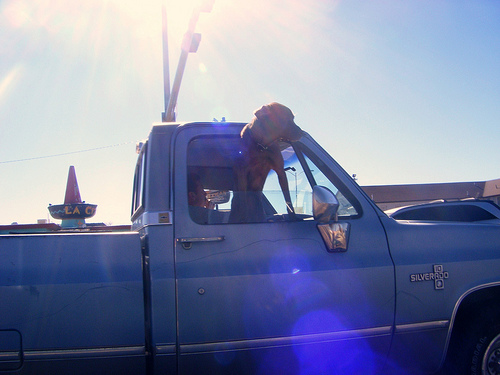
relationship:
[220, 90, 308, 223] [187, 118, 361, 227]
dog in window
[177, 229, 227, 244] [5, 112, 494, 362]
handle on truck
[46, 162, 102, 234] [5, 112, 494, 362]
sign by truck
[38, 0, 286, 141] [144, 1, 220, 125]
sun by pole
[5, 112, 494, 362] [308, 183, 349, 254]
truck has mirror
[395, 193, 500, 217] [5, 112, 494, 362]
vehicle by truck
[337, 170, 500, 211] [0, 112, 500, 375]
building past truck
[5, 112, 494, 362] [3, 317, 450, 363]
truck has stripe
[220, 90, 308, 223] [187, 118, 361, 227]
dog looking out window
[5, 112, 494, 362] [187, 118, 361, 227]
truck has window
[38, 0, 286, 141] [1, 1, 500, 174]
sun has sunshine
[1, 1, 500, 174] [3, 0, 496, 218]
sunshine visible in sky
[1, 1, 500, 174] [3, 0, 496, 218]
sunshine in sky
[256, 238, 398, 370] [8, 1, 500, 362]
circles on photo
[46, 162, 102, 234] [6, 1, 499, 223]
sign in distance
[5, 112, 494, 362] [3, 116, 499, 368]
truck has side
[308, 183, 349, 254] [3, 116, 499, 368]
mirror on side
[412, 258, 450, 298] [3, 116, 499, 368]
logo on side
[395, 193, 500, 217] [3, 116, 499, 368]
vehicle has side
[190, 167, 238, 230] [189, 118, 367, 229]
driver in front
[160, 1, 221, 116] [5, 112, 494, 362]
pole behind vehicle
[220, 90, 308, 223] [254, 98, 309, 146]
dog sticking out head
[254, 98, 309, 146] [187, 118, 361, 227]
head out of window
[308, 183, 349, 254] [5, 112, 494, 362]
mirror on truck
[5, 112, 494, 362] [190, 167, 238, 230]
truck has driver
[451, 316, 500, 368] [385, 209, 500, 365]
wheel in front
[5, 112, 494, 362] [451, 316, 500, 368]
truck has wheel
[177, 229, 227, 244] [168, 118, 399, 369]
handle for door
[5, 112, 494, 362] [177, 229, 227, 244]
truck has handle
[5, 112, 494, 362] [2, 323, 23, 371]
truck has tank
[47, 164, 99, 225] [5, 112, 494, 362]
sombrero back of truck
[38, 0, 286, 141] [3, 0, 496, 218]
sun in sky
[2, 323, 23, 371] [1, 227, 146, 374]
tank in bed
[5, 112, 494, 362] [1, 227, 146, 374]
truck has bed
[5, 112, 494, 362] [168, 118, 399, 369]
truck has door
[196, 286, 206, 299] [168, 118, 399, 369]
keyhole in door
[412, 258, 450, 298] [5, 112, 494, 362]
emblem on truck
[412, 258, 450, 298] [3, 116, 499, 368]
emblem on side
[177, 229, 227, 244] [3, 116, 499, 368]
handle on side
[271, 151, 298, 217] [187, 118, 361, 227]
leg in window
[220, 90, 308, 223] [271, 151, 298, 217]
dog has leg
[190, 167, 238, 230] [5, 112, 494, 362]
driver inside truck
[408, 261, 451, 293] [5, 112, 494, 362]
plate for truck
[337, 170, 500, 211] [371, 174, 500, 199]
building has roof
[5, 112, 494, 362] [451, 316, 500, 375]
truck has wheel